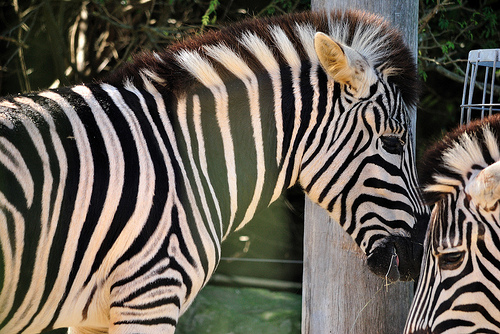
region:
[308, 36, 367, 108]
yellow fur inside ear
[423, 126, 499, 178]
mane is brown and white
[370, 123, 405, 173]
zebra eyes are black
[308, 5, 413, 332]
zebra standing in front of wooden pole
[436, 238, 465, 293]
eye of animal is closed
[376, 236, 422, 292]
mouth of animal is black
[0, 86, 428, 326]
black and white stripes on animal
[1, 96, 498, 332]
two animals in photo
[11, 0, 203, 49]
leaves of green in back of animals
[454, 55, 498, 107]
blue wired object next to smaller animal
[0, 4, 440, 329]
this is a zebra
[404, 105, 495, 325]
this is a zebra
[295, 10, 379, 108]
this is an ear of a zebra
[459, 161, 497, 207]
this is an ear of a zebra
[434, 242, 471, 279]
this is an eye of a zebra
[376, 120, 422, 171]
this is an eye of a zebra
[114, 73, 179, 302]
a black stripe on a zebra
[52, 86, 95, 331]
a black stripe on a zebra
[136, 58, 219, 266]
a black stripe on a zebra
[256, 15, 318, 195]
a black stripe on a zebra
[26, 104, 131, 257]
black and white color stripe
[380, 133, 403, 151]
eye of the zebra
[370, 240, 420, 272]
mouth of the zebra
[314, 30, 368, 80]
ear of the zebra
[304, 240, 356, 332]
grey color pole at background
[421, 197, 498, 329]
zebra with bend head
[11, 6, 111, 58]
plants at background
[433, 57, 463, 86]
branches of trees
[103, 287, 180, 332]
front leg of zebra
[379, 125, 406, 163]
This zebra has a dark black eye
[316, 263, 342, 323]
There is a pole here that is wooden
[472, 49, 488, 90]
There is a silver bucket here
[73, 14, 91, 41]
There is a green tree in the distance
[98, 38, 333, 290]
This photo was taken in the summer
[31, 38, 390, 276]
the sun shines on the zebra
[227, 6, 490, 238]
the zebra is by the pole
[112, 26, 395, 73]
the zebra has hair on the neckd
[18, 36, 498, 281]
two zebras are pictured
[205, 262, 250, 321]
the zebra is by a rock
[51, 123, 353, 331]
the zebra is black, white,a nd gray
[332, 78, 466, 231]
the zebra's eye is open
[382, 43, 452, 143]
the zebra has black hair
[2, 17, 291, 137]
leaves are on the branches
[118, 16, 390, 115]
black and white mane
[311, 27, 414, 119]
zebra has white ear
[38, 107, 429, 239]
black and white stripes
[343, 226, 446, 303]
black nose on zebra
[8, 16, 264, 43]
green and leafy trees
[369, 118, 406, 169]
zebra has black eye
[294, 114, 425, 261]
narrow stripes on zebra's face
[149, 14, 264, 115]
zebra has thick mane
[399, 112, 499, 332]
Black and white zebra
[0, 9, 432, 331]
Black and white zebra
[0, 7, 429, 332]
Black and white zebra in front of a zebra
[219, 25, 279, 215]
Black stripe on the zebra